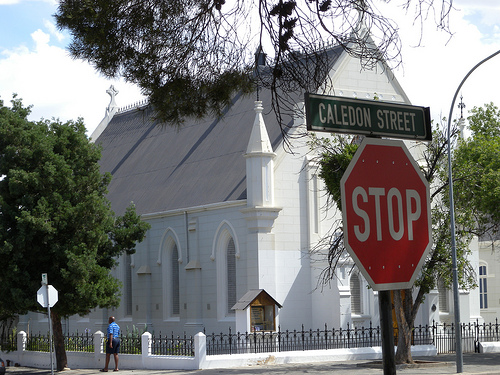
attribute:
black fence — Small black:
[203, 322, 493, 359]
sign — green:
[356, 151, 442, 274]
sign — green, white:
[304, 91, 431, 143]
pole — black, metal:
[378, 288, 400, 374]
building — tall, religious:
[86, 28, 486, 353]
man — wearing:
[99, 314, 118, 374]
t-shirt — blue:
[109, 323, 121, 338]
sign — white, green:
[304, 96, 441, 146]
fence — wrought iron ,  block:
[32, 297, 496, 373]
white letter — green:
[315, 101, 333, 128]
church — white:
[3, 14, 488, 373]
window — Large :
[223, 236, 238, 317]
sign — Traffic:
[36, 284, 58, 307]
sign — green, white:
[302, 90, 437, 141]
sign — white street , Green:
[287, 83, 440, 149]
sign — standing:
[341, 141, 433, 291]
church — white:
[54, 17, 447, 342]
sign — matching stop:
[36, 286, 58, 308]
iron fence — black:
[0, 318, 498, 360]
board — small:
[237, 283, 287, 334]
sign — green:
[300, 90, 434, 137]